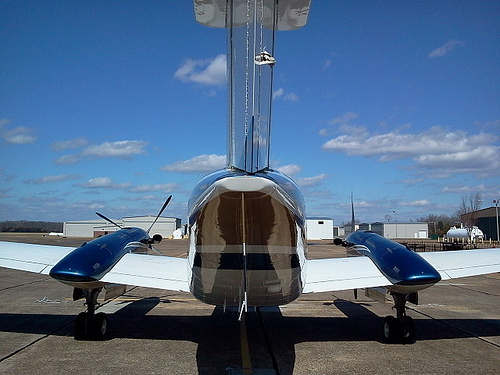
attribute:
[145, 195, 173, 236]
propeller — thin, black, long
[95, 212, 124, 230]
propeller — thin, black, long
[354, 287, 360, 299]
propeller — black, thin, long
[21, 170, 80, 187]
cloud — grey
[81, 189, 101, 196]
cloud — grey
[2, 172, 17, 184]
cloud — grey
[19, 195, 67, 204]
cloud — grey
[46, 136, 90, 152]
cloud — grey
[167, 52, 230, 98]
cloud — white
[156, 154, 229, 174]
cloud — white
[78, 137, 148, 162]
cloud — white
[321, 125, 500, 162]
cloud — white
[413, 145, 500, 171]
cloud — white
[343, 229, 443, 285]
engine — blue, metallic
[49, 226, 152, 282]
engine — blue, metallic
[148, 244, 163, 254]
propeller — thin, black, long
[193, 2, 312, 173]
tail — metallic, silver, blue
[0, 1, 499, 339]
jet — parked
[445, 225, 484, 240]
tank — white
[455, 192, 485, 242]
tree — skinny, bare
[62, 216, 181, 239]
building — grey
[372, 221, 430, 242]
building — grey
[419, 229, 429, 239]
door — white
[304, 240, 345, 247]
propeller — thin, long, black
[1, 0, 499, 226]
sky — blue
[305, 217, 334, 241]
building — white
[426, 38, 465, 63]
cloud — white, wispy, small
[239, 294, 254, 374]
line — yellow, painted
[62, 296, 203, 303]
line — yellow, painted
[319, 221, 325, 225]
rectangle — black, small